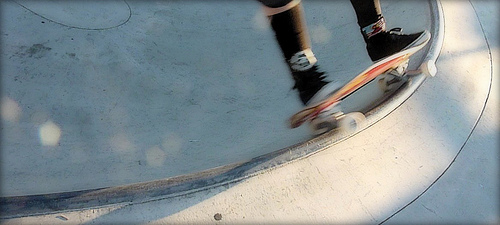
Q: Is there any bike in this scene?
A: No, there are no bikes.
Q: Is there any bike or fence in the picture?
A: No, there are no bikes or fences.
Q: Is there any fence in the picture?
A: No, there are no fences.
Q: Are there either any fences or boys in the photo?
A: No, there are no fences or boys.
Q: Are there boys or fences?
A: No, there are no fences or boys.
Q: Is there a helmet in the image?
A: No, there are no helmets.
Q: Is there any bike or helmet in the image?
A: No, there are no helmets or bikes.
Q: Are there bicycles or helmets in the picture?
A: No, there are no helmets or bicycles.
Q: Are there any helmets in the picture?
A: No, there are no helmets.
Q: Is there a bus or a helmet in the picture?
A: No, there are no helmets or buses.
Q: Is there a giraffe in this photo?
A: No, there are no giraffes.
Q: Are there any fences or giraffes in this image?
A: No, there are no giraffes or fences.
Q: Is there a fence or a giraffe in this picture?
A: No, there are no giraffes or fences.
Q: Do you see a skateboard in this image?
A: Yes, there is a skateboard.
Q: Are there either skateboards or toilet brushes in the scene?
A: Yes, there is a skateboard.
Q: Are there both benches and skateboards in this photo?
A: No, there is a skateboard but no benches.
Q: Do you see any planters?
A: No, there are no planters.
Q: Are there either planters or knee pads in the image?
A: No, there are no planters or knee pads.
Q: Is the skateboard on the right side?
A: Yes, the skateboard is on the right of the image.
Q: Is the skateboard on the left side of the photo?
A: No, the skateboard is on the right of the image.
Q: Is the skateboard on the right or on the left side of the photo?
A: The skateboard is on the right of the image.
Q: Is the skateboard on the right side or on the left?
A: The skateboard is on the right of the image.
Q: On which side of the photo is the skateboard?
A: The skateboard is on the right of the image.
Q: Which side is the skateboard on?
A: The skateboard is on the right of the image.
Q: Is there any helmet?
A: No, there are no helmets.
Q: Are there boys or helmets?
A: No, there are no helmets or boys.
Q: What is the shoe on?
A: The shoe is on the skateboard.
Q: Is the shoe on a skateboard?
A: Yes, the shoe is on a skateboard.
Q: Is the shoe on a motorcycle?
A: No, the shoe is on a skateboard.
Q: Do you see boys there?
A: No, there are no boys.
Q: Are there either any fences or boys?
A: No, there are no boys or fences.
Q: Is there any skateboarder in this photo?
A: Yes, there is a skateboarder.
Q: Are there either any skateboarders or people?
A: Yes, there is a skateboarder.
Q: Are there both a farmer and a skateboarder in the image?
A: No, there is a skateboarder but no farmers.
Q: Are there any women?
A: No, there are no women.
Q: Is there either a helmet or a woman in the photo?
A: No, there are no women or helmets.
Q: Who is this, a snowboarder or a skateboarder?
A: This is a skateboarder.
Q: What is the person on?
A: The skateboarder is on the skateboard.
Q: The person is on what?
A: The skateboarder is on the skateboard.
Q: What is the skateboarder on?
A: The skateboarder is on the skateboard.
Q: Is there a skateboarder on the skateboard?
A: Yes, there is a skateboarder on the skateboard.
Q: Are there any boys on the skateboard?
A: No, there is a skateboarder on the skateboard.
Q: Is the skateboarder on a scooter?
A: No, the skateboarder is on the skateboard.